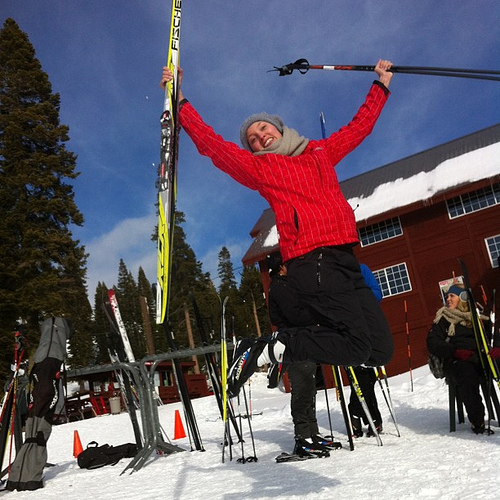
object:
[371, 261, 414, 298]
window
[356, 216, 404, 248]
window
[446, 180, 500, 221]
window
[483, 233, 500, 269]
window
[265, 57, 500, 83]
ski sticks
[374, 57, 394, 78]
left hand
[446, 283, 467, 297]
headband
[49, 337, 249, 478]
rack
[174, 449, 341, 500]
shadow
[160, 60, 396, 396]
person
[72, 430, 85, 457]
orange cone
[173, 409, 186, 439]
orange cone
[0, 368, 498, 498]
snow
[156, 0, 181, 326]
skis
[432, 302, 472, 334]
scarf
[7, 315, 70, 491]
bag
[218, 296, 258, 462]
ski poles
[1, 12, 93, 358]
pine tree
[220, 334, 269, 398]
snow shoe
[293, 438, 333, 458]
snow shoe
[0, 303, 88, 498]
ski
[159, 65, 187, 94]
hand.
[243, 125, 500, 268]
roof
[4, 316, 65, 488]
skis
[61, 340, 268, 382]
rail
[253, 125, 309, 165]
scarf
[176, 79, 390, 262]
coat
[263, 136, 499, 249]
snow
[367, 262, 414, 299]
cross bars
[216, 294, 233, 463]
skis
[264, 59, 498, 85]
stick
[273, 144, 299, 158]
neck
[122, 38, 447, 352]
air